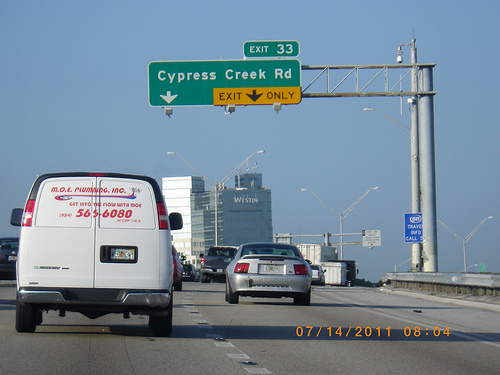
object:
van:
[11, 168, 184, 334]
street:
[1, 332, 205, 374]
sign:
[43, 183, 146, 226]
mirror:
[167, 211, 184, 229]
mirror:
[13, 209, 25, 226]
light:
[156, 202, 169, 234]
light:
[21, 198, 39, 230]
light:
[232, 261, 252, 275]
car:
[222, 242, 312, 305]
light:
[293, 263, 312, 277]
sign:
[241, 40, 299, 57]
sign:
[214, 85, 301, 105]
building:
[164, 176, 202, 276]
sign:
[403, 213, 423, 242]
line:
[192, 311, 278, 374]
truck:
[311, 261, 325, 284]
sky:
[15, 33, 145, 134]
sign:
[150, 61, 302, 107]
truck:
[199, 242, 237, 283]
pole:
[407, 35, 419, 211]